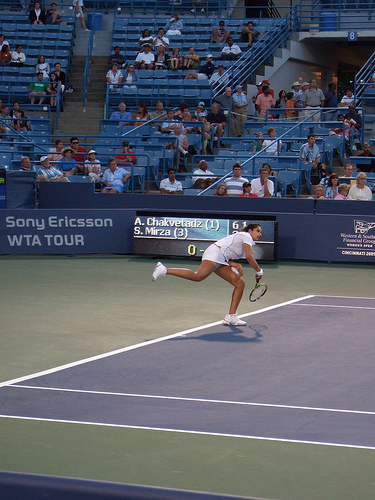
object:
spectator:
[100, 157, 134, 195]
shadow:
[163, 320, 264, 343]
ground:
[2, 254, 374, 499]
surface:
[3, 293, 373, 455]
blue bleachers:
[138, 71, 213, 98]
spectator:
[204, 105, 227, 138]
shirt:
[224, 176, 249, 195]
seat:
[239, 158, 255, 175]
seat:
[280, 169, 299, 185]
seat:
[212, 168, 229, 177]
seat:
[219, 149, 236, 158]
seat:
[289, 138, 301, 153]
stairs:
[51, 26, 114, 152]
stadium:
[0, 0, 374, 499]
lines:
[0, 411, 375, 452]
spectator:
[246, 165, 278, 197]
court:
[2, 292, 372, 448]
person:
[58, 147, 78, 177]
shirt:
[57, 156, 76, 170]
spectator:
[192, 157, 218, 191]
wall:
[3, 202, 357, 265]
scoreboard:
[133, 210, 274, 243]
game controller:
[150, 223, 268, 326]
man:
[299, 129, 326, 179]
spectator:
[307, 184, 328, 199]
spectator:
[346, 170, 372, 199]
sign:
[132, 216, 229, 241]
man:
[302, 77, 325, 122]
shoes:
[152, 261, 165, 282]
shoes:
[222, 314, 247, 327]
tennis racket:
[249, 271, 268, 304]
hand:
[254, 270, 264, 280]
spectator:
[239, 181, 257, 198]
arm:
[244, 237, 262, 274]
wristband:
[256, 268, 263, 275]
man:
[159, 165, 184, 196]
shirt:
[160, 177, 184, 192]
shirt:
[300, 143, 320, 162]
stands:
[1, 0, 373, 201]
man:
[225, 161, 247, 195]